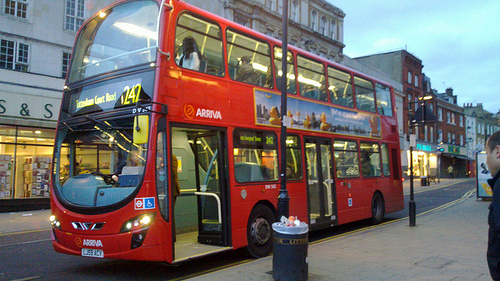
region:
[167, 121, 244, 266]
the open doorway of a bus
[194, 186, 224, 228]
the safety handle in the bus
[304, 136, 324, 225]
the door of a bus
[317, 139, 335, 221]
the door of a bus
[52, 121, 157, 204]
the large window of a bus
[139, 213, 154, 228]
the headlight of a bus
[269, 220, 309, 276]
a black trash can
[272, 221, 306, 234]
a white trash bag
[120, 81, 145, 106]
a yellow number 247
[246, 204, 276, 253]
a bus tire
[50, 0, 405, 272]
a red double decker bus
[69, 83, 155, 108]
the bus street route and number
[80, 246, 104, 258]
the buses registered tag number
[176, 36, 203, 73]
a passenger in the upper deck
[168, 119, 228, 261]
the buses front door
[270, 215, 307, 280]
a grey trash can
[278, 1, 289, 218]
a light post at the street curb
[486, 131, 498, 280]
a man standing on the sidewalk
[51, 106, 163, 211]
the front windshield of the driver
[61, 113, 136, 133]
the buses windshield wipers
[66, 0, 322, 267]
a double decker bus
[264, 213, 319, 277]
a trash can full of trash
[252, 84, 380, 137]
a picture on the side of a bus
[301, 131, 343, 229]
doors on a bus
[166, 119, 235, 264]
doors on a bus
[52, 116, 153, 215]
front window of a bus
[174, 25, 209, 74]
a passenger on a bus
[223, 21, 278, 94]
a window on a bus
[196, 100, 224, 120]
white letters on the side of a bus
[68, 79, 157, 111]
yellow letters on a bus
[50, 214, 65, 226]
The left headlights on the front of the bus.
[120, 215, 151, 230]
The right headlights on the front of the bus.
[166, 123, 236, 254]
The opened door on the side of the bus.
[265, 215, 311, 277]
The black trash can.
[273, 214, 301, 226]
The trash in the trash can.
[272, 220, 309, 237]
The white bag in the trash can.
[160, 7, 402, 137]
The second level of the bus.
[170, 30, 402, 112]
The passenger windows on the second level of the bus.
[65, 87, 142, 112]
The marquee display on the front of the bus.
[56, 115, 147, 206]
The front window of the bus.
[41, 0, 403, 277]
bus has 2 levels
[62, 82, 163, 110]
green lettering and numbers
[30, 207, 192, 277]
lights on bus are yellow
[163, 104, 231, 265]
bus doors are open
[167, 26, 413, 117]
people sitting on bus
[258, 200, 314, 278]
trash can is black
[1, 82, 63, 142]
black letters on building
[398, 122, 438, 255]
street lamp on sidewalk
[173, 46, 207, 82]
woman wearing white shirt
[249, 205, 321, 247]
white trash bag in trash can